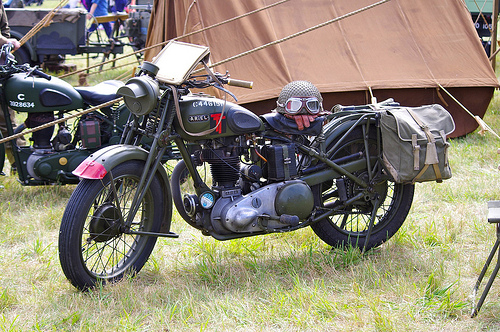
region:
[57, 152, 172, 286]
Front wheel of a motorcycle.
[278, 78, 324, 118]
Helmet on a motorcycle.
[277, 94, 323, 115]
Goggles on a helmet.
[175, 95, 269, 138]
Gas tank on a motorcycle.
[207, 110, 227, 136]
Red marks on a gas tank of a motorcycle.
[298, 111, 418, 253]
Back wheel of a motorcycle.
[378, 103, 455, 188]
Pack on the back of a motorcycle.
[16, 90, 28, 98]
The letter C on a gas tank.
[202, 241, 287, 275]
Grass underneath a motorcycle.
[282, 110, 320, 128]
Fingers of a glove sticking out under a helmet on a motorcycle.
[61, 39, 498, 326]
the bike is black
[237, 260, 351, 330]
the grass is green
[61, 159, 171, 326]
the tire is blac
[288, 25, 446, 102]
the tent is brown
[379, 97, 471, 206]
the bag is gray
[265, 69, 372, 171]
the helmet is on the seat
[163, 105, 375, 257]
the motor is black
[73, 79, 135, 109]
the seat is black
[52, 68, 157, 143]
the seat is made of leather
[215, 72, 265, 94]
the handle is brown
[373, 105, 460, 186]
Sack on the back end of a motorcycle.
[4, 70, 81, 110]
Gas tank on a motorcycle.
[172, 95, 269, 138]
Gas tank on a motorcycle with two red T's on it.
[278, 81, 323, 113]
Helmet on a motorcycle with goggles on it.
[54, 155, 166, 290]
Front wheel on a motorcycle.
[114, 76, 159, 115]
Front headlight on a motorcycle.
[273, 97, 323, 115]
Goggles on a helmet sitting on motorcycle.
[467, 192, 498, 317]
Part of a chair sitting in the grass.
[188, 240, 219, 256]
Grass under a motorcycle.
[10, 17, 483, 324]
There are motorcycles on the grass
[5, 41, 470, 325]
There are motorcycles in the photo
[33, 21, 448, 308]
There is a full view of one motorcycle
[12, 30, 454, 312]
There is a helmet on the motorcycle in the foreground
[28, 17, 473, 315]
The photo was taken during the day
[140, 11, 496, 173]
There is a brown tent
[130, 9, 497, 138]
There is a tent in the background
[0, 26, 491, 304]
The motorcycles are black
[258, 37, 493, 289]
There is a backpack on the bag of the motorcycle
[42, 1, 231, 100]
There are people in the background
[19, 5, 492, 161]
Military field soldier encampment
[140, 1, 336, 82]
Tent pitched soldier use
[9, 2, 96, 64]
Military vehicle truck bed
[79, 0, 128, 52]
Person blue shirt walking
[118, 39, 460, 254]
Type motorcycle specifically military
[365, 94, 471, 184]
Saddlebags anchored rear tire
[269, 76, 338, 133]
Safety helmet goggles gloves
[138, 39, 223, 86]
Mini windshield protect rider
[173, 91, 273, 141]
Gas tank military numbered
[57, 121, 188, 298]
Front tire covered red green